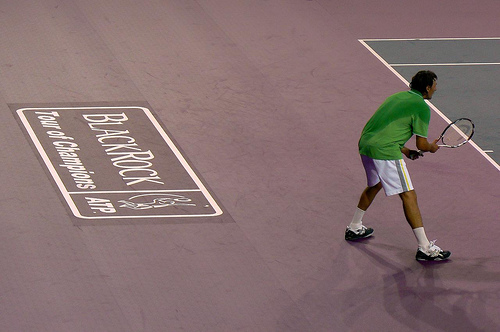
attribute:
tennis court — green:
[1, 1, 498, 330]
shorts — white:
[359, 152, 414, 195]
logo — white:
[12, 101, 224, 232]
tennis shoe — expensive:
[413, 240, 451, 265]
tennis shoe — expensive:
[342, 223, 374, 238]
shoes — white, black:
[346, 219, 373, 241]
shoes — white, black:
[413, 242, 450, 262]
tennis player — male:
[339, 68, 474, 264]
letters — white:
[33, 109, 166, 217]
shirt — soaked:
[352, 90, 432, 162]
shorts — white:
[360, 153, 416, 200]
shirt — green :
[354, 81, 435, 164]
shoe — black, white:
[414, 244, 452, 261]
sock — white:
[409, 224, 431, 255]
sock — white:
[347, 206, 368, 230]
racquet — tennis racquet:
[402, 111, 476, 156]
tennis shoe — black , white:
[414, 236, 451, 263]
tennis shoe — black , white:
[341, 222, 376, 242]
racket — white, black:
[434, 118, 473, 145]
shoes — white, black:
[338, 220, 453, 267]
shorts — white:
[352, 148, 409, 200]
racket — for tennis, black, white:
[410, 116, 484, 170]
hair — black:
[394, 44, 449, 93]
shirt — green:
[355, 86, 437, 161]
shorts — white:
[357, 145, 421, 196]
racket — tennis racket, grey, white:
[436, 116, 477, 148]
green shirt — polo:
[361, 89, 431, 166]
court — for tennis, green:
[2, 2, 496, 327]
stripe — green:
[393, 159, 411, 189]